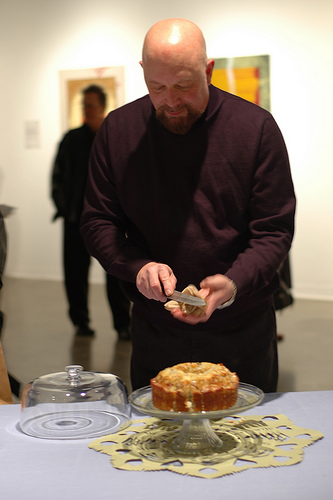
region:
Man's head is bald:
[129, 9, 219, 71]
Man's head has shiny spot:
[163, 18, 186, 54]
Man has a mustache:
[160, 103, 196, 113]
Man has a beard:
[152, 113, 212, 141]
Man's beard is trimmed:
[151, 109, 204, 138]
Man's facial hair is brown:
[153, 101, 212, 138]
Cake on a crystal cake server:
[131, 349, 280, 464]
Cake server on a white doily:
[103, 396, 320, 477]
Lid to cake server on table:
[17, 349, 134, 451]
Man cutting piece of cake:
[143, 263, 239, 334]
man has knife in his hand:
[151, 279, 232, 335]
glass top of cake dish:
[35, 359, 131, 431]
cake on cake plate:
[161, 355, 248, 483]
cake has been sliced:
[164, 358, 230, 415]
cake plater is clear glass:
[141, 397, 247, 463]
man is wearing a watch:
[203, 273, 243, 321]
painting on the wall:
[204, 45, 295, 117]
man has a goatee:
[146, 95, 238, 144]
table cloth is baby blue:
[26, 440, 123, 482]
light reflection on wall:
[55, 16, 132, 76]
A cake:
[164, 339, 255, 441]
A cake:
[154, 384, 224, 496]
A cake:
[166, 366, 240, 491]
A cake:
[174, 332, 229, 438]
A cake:
[166, 317, 287, 439]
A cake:
[170, 314, 224, 433]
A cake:
[183, 351, 280, 489]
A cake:
[130, 305, 214, 455]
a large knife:
[159, 284, 206, 306]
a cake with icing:
[149, 361, 240, 409]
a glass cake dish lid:
[24, 365, 133, 438]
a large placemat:
[92, 411, 323, 479]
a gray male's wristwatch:
[215, 279, 236, 309]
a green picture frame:
[207, 55, 269, 110]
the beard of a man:
[152, 106, 194, 135]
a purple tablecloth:
[0, 391, 332, 499]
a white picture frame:
[58, 69, 124, 131]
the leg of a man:
[62, 215, 95, 325]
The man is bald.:
[141, 14, 214, 133]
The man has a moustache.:
[128, 17, 218, 139]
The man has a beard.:
[134, 17, 222, 138]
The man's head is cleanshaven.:
[131, 12, 223, 139]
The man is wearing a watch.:
[217, 272, 240, 312]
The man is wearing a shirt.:
[64, 81, 302, 331]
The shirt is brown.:
[76, 75, 299, 334]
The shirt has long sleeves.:
[78, 76, 300, 334]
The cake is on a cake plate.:
[124, 357, 267, 455]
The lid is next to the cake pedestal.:
[10, 355, 272, 465]